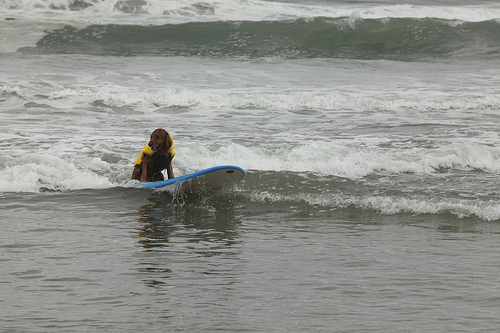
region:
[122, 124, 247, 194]
dog on a surfboard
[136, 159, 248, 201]
blue and white surfboard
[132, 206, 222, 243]
reflection in the water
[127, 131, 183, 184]
yellow life jacket on the dog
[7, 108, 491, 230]
small wave in the ocean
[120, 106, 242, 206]
a dog is sitting on a surfboard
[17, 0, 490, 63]
small wave heading toward the shore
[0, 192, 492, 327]
area of water close to the shore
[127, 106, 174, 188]
golden retriever wearing a life jacket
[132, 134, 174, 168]
yellow life jacket on the dog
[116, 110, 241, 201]
the dog is surfing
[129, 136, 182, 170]
dog wearing a life jacket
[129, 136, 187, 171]
the life jacket is yellow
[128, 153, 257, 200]
the surfboard is blue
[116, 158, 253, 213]
bottom half of surfboard in water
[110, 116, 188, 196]
the dog is brown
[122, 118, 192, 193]
dog is looking towards left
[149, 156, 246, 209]
bottom of surfboard is white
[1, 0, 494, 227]
waves behind the dog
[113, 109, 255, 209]
dog is in ocean by himself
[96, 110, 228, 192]
surfer on blue board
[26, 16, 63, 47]
white clouds in blue sky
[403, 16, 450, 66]
white clouds in blue sky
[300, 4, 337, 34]
white clouds in blue sky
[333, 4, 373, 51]
white clouds in blue sky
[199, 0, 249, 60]
white clouds in blue sky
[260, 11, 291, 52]
white clouds in blue sky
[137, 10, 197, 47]
white clouds in blue sky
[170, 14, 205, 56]
white clouds in blue sky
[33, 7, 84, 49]
white clouds in blue sky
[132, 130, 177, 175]
a dog on a surfboard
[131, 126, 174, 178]
a dog wearing a yellow life vest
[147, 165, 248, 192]
a blue and white surfboard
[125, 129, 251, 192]
a dog sitting on a surfboard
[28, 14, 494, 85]
a large wave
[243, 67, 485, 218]
waves in the water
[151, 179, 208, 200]
water splashing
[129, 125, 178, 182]
a brown dog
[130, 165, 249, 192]
a surfboard in the water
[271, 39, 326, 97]
white and green ocean waves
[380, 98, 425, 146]
white and green ocean waves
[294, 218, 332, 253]
white and green ocean waves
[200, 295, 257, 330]
white and green ocean waves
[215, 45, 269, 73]
white and green ocean waves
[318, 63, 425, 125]
white and green ocean waves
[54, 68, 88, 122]
white and green ocean waves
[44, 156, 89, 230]
white and green ocean waves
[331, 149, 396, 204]
white and green ocean waves